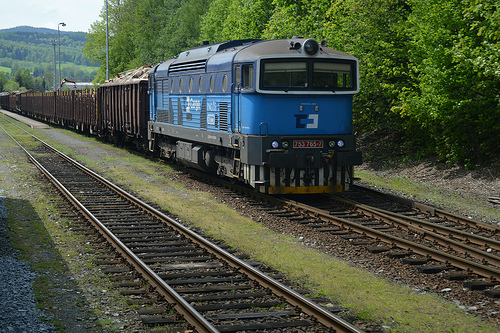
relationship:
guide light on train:
[302, 38, 321, 56] [59, 47, 388, 203]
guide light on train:
[303, 38, 320, 58] [49, 51, 354, 229]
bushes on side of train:
[358, 9, 498, 150] [70, 42, 457, 271]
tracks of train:
[276, 194, 497, 291] [0, 35, 363, 194]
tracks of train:
[4, 135, 304, 331] [0, 35, 363, 194]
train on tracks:
[0, 35, 363, 194] [259, 184, 497, 281]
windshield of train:
[266, 61, 352, 92] [140, 42, 372, 204]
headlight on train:
[269, 138, 281, 151] [0, 35, 363, 194]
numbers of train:
[289, 135, 325, 150] [0, 35, 363, 194]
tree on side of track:
[393, 0, 483, 178] [289, 183, 499, 284]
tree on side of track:
[321, 1, 417, 136] [289, 183, 499, 284]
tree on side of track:
[261, 0, 323, 38] [289, 183, 499, 284]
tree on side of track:
[219, 0, 274, 42] [289, 183, 499, 284]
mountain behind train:
[0, 25, 99, 93] [0, 35, 363, 194]